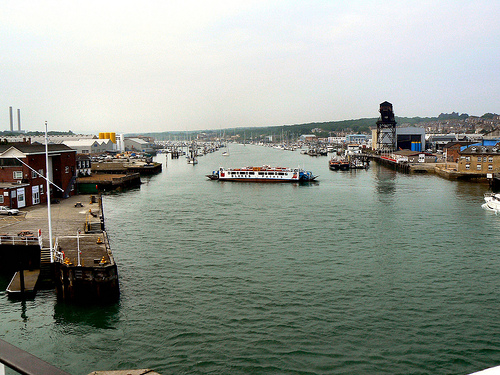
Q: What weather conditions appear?
A: It is clear.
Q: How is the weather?
A: It is clear.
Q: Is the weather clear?
A: Yes, it is clear.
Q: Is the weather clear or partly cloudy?
A: It is clear.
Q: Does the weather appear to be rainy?
A: No, it is clear.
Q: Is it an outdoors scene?
A: Yes, it is outdoors.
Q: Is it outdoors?
A: Yes, it is outdoors.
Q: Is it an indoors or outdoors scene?
A: It is outdoors.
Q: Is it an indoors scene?
A: No, it is outdoors.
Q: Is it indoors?
A: No, it is outdoors.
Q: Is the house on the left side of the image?
A: Yes, the house is on the left of the image.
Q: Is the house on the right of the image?
A: No, the house is on the left of the image.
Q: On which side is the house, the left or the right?
A: The house is on the left of the image.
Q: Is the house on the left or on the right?
A: The house is on the left of the image.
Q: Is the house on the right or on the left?
A: The house is on the left of the image.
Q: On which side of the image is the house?
A: The house is on the left of the image.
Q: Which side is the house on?
A: The house is on the left of the image.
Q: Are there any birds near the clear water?
A: No, there is a house near the water.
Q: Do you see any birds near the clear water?
A: No, there is a house near the water.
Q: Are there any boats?
A: Yes, there is a boat.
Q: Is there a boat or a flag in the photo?
A: Yes, there is a boat.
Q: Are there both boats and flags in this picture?
A: No, there is a boat but no flags.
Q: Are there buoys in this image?
A: No, there are no buoys.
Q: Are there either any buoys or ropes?
A: No, there are no buoys or ropes.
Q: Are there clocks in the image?
A: No, there are no clocks.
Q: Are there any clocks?
A: No, there are no clocks.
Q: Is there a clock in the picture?
A: No, there are no clocks.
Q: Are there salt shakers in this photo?
A: No, there are no salt shakers.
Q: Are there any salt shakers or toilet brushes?
A: No, there are no salt shakers or toilet brushes.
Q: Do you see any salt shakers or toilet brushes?
A: No, there are no salt shakers or toilet brushes.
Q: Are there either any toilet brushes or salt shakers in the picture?
A: No, there are no salt shakers or toilet brushes.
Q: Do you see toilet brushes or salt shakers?
A: No, there are no salt shakers or toilet brushes.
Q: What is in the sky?
A: The clouds are in the sky.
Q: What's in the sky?
A: The clouds are in the sky.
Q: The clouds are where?
A: The clouds are in the sky.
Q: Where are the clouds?
A: The clouds are in the sky.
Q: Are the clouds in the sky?
A: Yes, the clouds are in the sky.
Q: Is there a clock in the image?
A: No, there are no clocks.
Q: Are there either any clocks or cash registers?
A: No, there are no clocks or cash registers.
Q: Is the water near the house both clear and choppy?
A: No, the water is clear but calm.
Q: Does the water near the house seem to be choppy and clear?
A: No, the water is clear but calm.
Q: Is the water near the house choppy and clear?
A: No, the water is clear but calm.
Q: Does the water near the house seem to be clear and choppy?
A: No, the water is clear but calm.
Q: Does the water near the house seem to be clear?
A: Yes, the water is clear.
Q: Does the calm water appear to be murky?
A: No, the water is clear.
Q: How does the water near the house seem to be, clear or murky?
A: The water is clear.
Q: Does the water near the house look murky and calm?
A: No, the water is calm but clear.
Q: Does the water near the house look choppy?
A: No, the water is calm.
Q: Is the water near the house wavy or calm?
A: The water is calm.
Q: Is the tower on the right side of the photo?
A: Yes, the tower is on the right of the image.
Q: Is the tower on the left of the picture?
A: No, the tower is on the right of the image.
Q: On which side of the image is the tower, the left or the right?
A: The tower is on the right of the image.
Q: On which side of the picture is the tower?
A: The tower is on the right of the image.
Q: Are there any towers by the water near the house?
A: Yes, there is a tower by the water.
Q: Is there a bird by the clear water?
A: No, there is a tower by the water.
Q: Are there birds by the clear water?
A: No, there is a tower by the water.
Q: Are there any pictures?
A: No, there are no pictures.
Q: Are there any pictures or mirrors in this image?
A: No, there are no pictures or mirrors.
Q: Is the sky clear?
A: Yes, the sky is clear.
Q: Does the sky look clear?
A: Yes, the sky is clear.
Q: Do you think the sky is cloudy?
A: No, the sky is clear.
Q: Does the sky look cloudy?
A: No, the sky is clear.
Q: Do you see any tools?
A: No, there are no tools.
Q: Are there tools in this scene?
A: No, there are no tools.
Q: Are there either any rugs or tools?
A: No, there are no tools or rugs.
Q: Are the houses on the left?
A: Yes, the houses are on the left of the image.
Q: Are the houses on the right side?
A: No, the houses are on the left of the image.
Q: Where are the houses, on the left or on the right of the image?
A: The houses are on the left of the image.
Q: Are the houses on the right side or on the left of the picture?
A: The houses are on the left of the image.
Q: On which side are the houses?
A: The houses are on the left of the image.